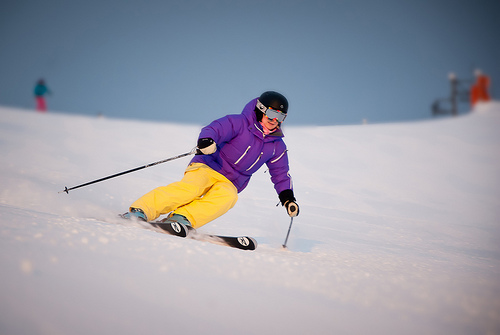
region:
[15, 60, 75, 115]
A skier in the background.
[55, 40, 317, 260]
The person is skiing down the slope.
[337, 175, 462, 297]
The snow is white.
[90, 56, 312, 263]
The person is holding ski poles.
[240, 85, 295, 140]
A black helmet.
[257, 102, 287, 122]
Goggles are protecting the person's eyes.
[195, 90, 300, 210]
The person is wearing a purple coat.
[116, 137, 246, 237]
The person has yellow snow pants on.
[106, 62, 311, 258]
The person is leaning to their left.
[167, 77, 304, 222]
The person is wearing black and white gloves.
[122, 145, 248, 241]
These are yellow pants.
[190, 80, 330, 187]
This a purple jacket.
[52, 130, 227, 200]
This is the right ski pole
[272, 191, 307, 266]
This is the left ski pole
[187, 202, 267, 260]
This is the left ski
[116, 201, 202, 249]
This is the right ski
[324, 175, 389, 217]
This is white snow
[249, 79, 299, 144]
This is a black hat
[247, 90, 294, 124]
These are gray goggles.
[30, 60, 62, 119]
This is a person in pink pants.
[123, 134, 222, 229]
Skier is wearing yellow pants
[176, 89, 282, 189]
Skier wearing purple jacket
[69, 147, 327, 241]
Ski poles in each hand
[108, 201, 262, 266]
Person wearing two skis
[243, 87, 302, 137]
Goggles around person's head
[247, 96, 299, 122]
Skier is wearing black helmet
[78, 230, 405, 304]
Ground covered in snow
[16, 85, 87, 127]
Person in red pants in the background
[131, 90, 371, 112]
Blue sky in the background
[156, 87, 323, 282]
Person is skiing down the slopes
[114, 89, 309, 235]
skier wearing purple coat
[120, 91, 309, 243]
skier wearing yellow snow pants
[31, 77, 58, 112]
skier wearing pink snow pants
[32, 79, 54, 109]
skier wearing blue coat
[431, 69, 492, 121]
ski lift in the background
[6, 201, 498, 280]
ski prints in the snow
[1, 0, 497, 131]
sky is clear of clouds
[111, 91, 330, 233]
skier is leaning into a turn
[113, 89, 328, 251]
skier is happily smiling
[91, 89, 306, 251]
skier is wearing black skis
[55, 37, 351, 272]
skier making a curve on the slope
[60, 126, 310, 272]
poles in back of body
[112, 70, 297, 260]
colorful outfit of purple jacket and yellow pants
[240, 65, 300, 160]
skier with grey goggles over eyes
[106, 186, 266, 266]
skier leaning on sides of skis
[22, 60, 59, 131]
person wearing red at top of hill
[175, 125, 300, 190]
zippers on front and sleeve of jacket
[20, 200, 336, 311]
dots of whiter snow on blueish snow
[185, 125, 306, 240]
gloved hands holding poles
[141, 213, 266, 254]
bottom of skis black and white